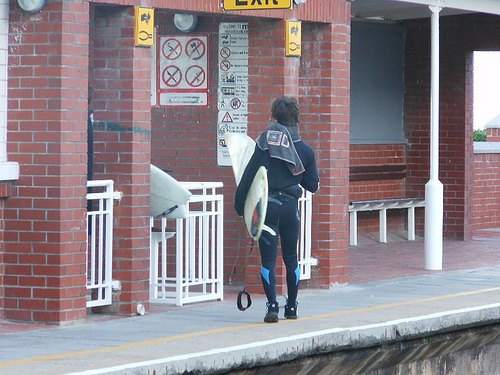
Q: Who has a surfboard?
A: A surfer.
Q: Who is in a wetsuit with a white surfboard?
A: Surfer.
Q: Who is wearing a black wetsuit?
A: Surfer.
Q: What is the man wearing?
A: Full wetsuit.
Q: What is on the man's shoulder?
A: Towel.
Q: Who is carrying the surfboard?
A: Man in wetsuit.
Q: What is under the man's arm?
A: White surfboard.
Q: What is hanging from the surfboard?
A: Black leash.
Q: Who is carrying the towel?
A: Man in the wetsuit.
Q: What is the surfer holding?
A: Surfboard.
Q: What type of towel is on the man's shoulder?
A: Black and red towel.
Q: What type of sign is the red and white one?
A: Warning sign.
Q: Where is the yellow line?
A: On the ground.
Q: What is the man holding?
A: Surfboard.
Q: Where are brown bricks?
A: On a building.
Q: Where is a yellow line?
A: On the ground.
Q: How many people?
A: One.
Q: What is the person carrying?
A: Surfboard.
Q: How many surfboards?
A: Two.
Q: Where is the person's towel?
A: Over shoulder.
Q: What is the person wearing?
A: Wetsuit.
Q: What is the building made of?
A: Brick.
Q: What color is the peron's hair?
A: Black.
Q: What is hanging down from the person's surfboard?
A: Wrist strap.